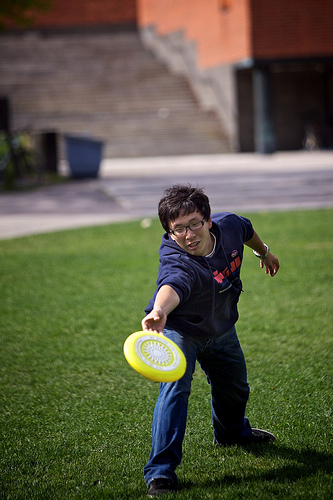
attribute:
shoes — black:
[147, 478, 174, 498]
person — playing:
[130, 194, 275, 440]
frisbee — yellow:
[57, 300, 197, 400]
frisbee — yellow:
[123, 330, 188, 380]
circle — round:
[120, 328, 187, 382]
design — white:
[136, 332, 181, 373]